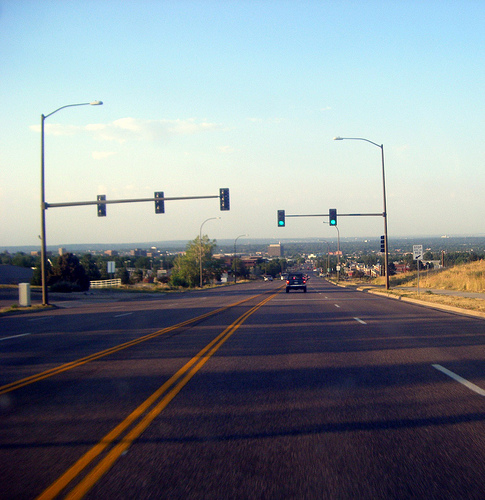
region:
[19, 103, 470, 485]
Lightly traveled highway shot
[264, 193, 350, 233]
Two streetlights facing camera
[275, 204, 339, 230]
Two street lights lit green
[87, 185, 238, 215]
Three street lights facing away from camera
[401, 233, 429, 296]
White and black street sign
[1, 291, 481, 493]
Black paved four lane highway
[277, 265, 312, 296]
SUV with taillights lit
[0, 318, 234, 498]
Yellow no passing stripes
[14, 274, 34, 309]
Grey metal signal box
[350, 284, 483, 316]
Cement curb lining street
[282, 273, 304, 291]
car on the road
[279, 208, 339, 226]
traffic light are green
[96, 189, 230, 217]
traffic lights on pole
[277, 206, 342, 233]
traffic lights on pole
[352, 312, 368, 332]
white stripes on street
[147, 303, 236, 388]
yellow stripes on rad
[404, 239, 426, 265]
sign is on roadside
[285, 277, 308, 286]
back light are red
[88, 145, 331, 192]
sky is blue and clear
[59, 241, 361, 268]
background has smal buildings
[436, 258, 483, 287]
the grass is light brown.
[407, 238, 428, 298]
a white and black street sign.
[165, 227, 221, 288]
a bunch of trees.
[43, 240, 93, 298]
a big dark green tree bush.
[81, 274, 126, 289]
a long thin white fence.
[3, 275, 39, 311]
a grey parking meter.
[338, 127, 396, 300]
a brown thin street light pole.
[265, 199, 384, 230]
two street lights are on green.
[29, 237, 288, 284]
a whole bunch of buildings.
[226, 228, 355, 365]
a dark blue vehicle is driving down the street.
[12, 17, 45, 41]
white clouds in blue sky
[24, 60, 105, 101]
white clouds in blue sky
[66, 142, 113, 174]
white clouds in blue sky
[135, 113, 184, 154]
white clouds in blue sky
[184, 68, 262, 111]
white clouds in blue sky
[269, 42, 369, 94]
white clouds in blue sky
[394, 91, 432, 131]
white clouds in blue sky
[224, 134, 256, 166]
white clouds in blue sky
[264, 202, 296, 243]
green signal light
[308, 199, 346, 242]
green sgnal light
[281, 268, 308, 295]
A vehicle is on a road.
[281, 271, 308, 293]
The colors of a vehicle are blue, black, and red.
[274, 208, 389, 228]
Two traffic lights are hanging from a post.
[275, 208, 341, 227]
Two traffic light's signals are green.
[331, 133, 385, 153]
A lamppost is suspended from a pole.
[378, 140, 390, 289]
The color of a pole is gray.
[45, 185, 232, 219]
Three traffic lights are hanging from a post.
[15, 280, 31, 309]
A white object is next to a road.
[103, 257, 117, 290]
A sign is at an intersection.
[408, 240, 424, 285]
A white and black sign is next to a road.